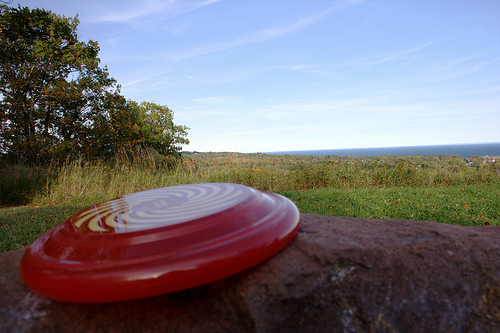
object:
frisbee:
[20, 182, 300, 302]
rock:
[0, 214, 500, 333]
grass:
[0, 151, 500, 253]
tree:
[0, 0, 189, 170]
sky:
[7, 0, 500, 156]